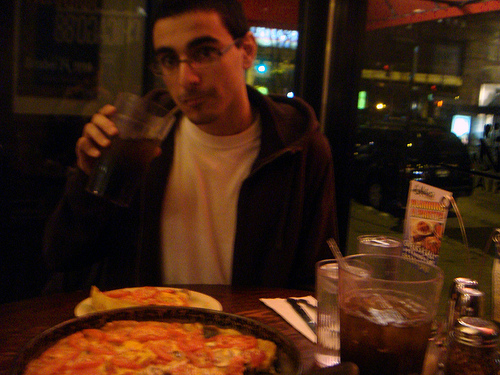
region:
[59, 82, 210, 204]
man holding drink in his hand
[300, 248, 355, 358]
water glass on table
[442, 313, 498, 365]
red pepper flakes on in jar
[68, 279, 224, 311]
slice of pizza on white plate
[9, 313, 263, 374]
whole pizza in pizza pan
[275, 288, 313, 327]
silverware on white napkin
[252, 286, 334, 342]
white napkin on brown table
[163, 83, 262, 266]
man wearing white t-shirt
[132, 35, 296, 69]
man wearing eye glasses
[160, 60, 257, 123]
man with facial hair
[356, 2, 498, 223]
outside window of restaurant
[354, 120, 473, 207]
SUV truck parked outside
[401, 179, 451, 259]
small sign about restaurant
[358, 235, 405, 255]
full glass of water left of man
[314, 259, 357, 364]
full glass in front of man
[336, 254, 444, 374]
glass of soda in foreground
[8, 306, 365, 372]
deep dish pizza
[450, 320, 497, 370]
a spice shaker, bottom left corner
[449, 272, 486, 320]
salt and pepper shaker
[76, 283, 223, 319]
plate of pizza front of man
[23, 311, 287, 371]
Pizza on a tray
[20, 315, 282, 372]
Pizza is on a tray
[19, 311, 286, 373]
Tomatoes on a pizza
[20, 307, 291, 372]
Tomatoes are on a pizza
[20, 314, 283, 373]
Sliced tomatoes on a pizza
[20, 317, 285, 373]
Sliced tomatoes are on a pizza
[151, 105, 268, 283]
Man wearing a shirt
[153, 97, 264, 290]
Man is wearing a shirt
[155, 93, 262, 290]
Man wearing a white shirt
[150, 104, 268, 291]
Man is wearing a white shirt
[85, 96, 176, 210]
A clear cup a man is holding.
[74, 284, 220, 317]
A white plate in front of a man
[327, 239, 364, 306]
Clear straw in a cup on the table.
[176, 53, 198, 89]
Nose on a man's face.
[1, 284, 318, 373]
A round brown table the man is sitting at.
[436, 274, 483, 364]
Silver top salt and pepper shakers.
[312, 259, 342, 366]
A clear plastic cup of water.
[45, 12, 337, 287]
A man with glasses drinking from a straw at a table.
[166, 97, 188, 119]
Clear straw going from the guy's mouth to cup.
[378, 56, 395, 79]
Small light on a pole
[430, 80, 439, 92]
Small light on a pole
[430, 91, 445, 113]
Small light on a pole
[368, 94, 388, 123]
Small light on a pole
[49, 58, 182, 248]
Dark liquid inside clear cup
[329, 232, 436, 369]
Dark liquid inside clear cup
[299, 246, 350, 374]
Dark liquid inside clear cup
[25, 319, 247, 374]
Pizza inside pizza pan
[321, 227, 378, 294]
Clear straw inside drink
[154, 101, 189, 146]
Clear straw inside drink